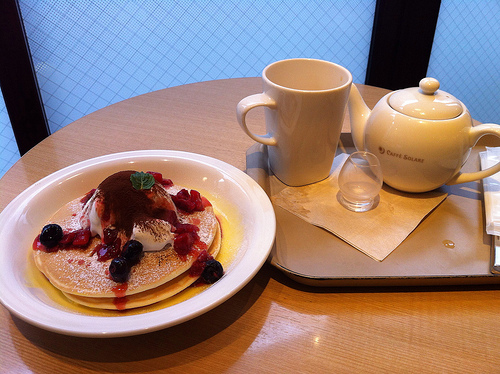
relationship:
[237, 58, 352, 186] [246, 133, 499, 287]
cup on top of tray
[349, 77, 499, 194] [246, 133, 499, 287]
teapot on top of tray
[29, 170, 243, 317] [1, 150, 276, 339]
food inside of bowl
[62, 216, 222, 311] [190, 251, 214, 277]
pancake under fruit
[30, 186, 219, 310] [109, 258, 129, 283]
pancake under fruit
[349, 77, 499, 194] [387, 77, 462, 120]
teapot has top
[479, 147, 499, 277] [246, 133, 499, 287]
items on top of tray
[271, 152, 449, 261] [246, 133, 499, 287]
napkin lying on tray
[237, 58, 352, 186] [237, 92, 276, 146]
cup has handle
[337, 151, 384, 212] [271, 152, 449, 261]
glass on top of napkin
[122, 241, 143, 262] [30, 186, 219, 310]
fruit on top of pancake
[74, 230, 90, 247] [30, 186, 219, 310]
fruit on top of pancake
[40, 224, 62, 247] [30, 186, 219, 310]
fruit on top of pancake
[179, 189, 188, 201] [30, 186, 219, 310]
fruit on top of pancake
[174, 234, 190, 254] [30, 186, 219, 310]
fruit on top of pancake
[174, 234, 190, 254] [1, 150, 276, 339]
fruit on bowl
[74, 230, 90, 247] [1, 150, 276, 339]
fruit on bowl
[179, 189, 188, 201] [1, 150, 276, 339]
fruit on bowl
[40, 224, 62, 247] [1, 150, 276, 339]
fruit on bowl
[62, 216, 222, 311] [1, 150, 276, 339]
pancake on top of bowl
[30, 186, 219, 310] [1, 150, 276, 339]
pancake on top of bowl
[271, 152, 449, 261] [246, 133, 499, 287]
napkin on top of tray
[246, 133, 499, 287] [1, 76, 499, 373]
tray on top of table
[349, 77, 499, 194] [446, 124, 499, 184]
teapot has handle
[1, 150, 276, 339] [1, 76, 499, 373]
bowl on top of table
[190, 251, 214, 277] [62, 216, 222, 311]
fruit on top of pancake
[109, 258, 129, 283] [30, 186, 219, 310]
fruit on top of pancake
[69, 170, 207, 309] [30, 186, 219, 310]
syrup on top of pancake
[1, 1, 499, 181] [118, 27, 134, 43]
screen has rhombus design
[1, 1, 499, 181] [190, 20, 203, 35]
screen has rhombus design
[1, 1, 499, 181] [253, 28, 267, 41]
screen has rhombus design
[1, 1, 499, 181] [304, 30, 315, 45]
screen has rhombus design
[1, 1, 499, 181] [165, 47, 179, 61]
screen has rhombus design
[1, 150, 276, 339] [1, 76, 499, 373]
bowl on table